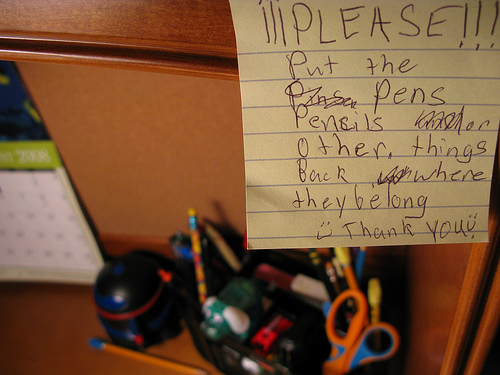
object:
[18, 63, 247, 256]
board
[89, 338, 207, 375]
pencil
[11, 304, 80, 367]
table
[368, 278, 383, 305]
eraser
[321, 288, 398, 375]
holder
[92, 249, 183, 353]
bank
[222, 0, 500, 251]
note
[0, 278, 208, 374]
desk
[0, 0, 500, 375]
calender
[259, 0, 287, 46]
mark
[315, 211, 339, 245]
face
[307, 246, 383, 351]
pen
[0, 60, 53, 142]
picture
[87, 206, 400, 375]
supplies